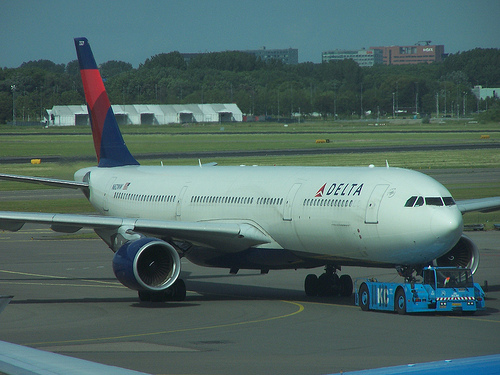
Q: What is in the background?
A: Tall buildings.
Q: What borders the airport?
A: A tall wire fence.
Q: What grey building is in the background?
A: An airplane hangar.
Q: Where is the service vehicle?
A: Underneath the airplane.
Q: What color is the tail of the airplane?
A: Red, orange, brown, and blue.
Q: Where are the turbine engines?
A: Under the wings.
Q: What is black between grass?
A: Paths at airport.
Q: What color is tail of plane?
A: Red and blue.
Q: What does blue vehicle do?
A: Push plane out.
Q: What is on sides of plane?
A: Wings.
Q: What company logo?
A: Delta.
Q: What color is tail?
A: Red blue and maroon.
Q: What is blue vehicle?
A: Tow truck for planes.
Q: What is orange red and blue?
A: Tail.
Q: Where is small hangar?
A: In the distance.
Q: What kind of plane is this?
A: Delta.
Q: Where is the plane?
A: At the airport.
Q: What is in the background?
A: A field.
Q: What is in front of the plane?
A: A blue service truck.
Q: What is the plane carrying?
A: Passengers.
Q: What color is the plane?
A: White.